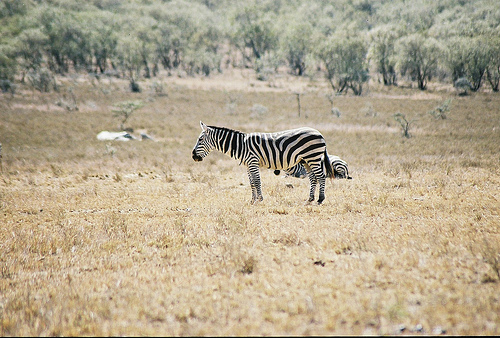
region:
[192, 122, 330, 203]
zebra is standing around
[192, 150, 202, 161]
snout of a zebra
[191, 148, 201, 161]
the snout is black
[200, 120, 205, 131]
ear of a zebra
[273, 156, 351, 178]
zebra is lying down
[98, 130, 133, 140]
a brightly lit rock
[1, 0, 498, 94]
a whole bunch of trees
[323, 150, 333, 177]
the tail is black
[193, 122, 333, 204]
the zebra is striped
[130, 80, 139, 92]
the bush is dark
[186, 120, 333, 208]
a zebra standing in the middle of the field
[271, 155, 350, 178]
another zebra laying down on the ground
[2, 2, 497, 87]
the trees far away from the field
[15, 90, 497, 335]
the big field for the zebras to stand in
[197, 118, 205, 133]
the ear of the zebra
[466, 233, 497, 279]
the little branches on the bush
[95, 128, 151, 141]
some rocks by the little tree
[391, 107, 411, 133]
another tiny little tree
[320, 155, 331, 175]
the tail of the zebra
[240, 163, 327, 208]
the legs of the zebra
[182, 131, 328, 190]
white and black zebra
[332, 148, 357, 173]
white and black zebra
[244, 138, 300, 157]
white and black stripes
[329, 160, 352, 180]
white and black stripes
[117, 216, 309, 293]
brown grass in field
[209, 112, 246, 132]
stiff mane on zebra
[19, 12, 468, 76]
trees growing in background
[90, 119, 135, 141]
large rocks on field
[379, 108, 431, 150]
small bushes in field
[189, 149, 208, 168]
black nose on zebra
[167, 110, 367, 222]
zebras in the wild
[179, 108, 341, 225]
a black and white stripes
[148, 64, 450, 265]
two zebra in a field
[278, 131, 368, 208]
one zebra is laying down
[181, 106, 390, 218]
one zebra is standing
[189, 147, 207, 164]
black nose of zebra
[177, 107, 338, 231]
white zebra with black stripes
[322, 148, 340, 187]
black hairs on tail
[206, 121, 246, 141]
short mane on neck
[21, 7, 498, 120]
several trees in the distance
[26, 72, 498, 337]
dead grass on the ground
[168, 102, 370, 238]
a standing zebra in a field